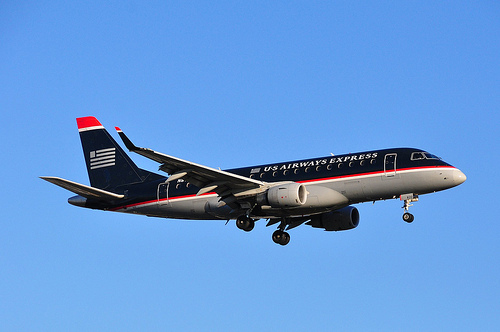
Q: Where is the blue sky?
A: Behind the plane.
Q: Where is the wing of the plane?
A: On the left side.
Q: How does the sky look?
A: Clear.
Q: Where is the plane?
A: In the sky.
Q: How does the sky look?
A: Blue.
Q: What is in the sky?
A: A jet.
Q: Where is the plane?
A: In the sky.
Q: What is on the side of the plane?
A: A wing.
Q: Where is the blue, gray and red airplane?
A: In the sky.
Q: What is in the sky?
A: A plane.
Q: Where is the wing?
A: On side of the plane.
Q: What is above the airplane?
A: Blue sky.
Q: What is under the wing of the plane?
A: The engine.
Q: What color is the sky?
A: Blue.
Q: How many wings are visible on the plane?
A: Two.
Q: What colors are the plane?
A: Navy blue, red, and gray.